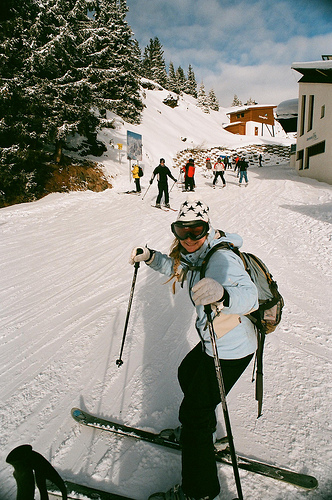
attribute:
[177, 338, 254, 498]
pants — black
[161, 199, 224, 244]
hat — black, white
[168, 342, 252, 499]
pants — blackish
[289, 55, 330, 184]
building — behind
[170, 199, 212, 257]
woman — blue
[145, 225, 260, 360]
sweater — light blue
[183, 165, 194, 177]
jacket — red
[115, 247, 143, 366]
rod — black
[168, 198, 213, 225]
cap — white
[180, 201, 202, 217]
stars — black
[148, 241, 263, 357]
jacket — blue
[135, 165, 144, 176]
backpack — black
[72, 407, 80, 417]
logo — blue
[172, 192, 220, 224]
hat — with stars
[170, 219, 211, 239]
ski goggles — black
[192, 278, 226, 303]
glove — white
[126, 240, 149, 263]
glove — white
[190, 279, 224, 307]
glove — grey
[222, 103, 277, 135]
lodge — ski